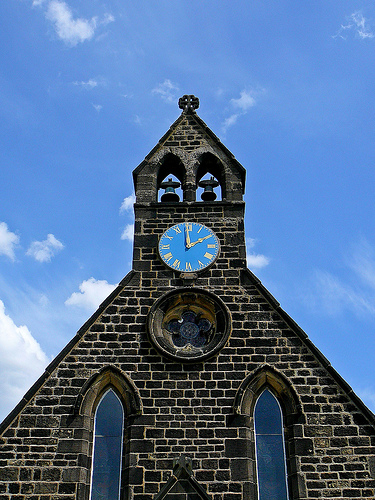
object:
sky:
[0, 3, 375, 427]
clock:
[157, 221, 221, 273]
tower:
[131, 94, 248, 274]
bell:
[160, 177, 181, 202]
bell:
[198, 176, 220, 200]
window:
[74, 362, 143, 499]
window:
[233, 362, 307, 500]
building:
[0, 94, 374, 499]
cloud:
[0, 220, 65, 426]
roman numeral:
[170, 225, 182, 234]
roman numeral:
[196, 224, 204, 234]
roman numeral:
[207, 243, 216, 248]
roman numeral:
[172, 258, 181, 268]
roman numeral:
[161, 243, 170, 250]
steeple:
[178, 93, 200, 116]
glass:
[253, 388, 290, 499]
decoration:
[147, 285, 233, 363]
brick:
[125, 439, 155, 454]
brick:
[225, 438, 256, 460]